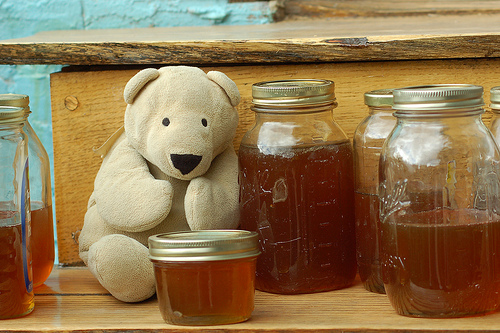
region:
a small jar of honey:
[139, 209, 281, 327]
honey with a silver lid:
[120, 199, 255, 324]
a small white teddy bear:
[62, 77, 242, 285]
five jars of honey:
[177, 70, 497, 332]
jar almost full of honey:
[244, 87, 351, 297]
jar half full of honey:
[346, 89, 488, 304]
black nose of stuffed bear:
[147, 143, 210, 188]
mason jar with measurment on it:
[222, 75, 340, 312]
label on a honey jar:
[17, 157, 48, 326]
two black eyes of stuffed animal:
[135, 105, 215, 137]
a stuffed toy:
[77, 101, 180, 331]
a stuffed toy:
[159, 34, 244, 215]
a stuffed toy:
[102, 56, 230, 328]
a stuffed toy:
[192, 110, 294, 280]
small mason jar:
[129, 223, 286, 308]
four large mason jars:
[242, 58, 495, 264]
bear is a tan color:
[74, 53, 257, 320]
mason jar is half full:
[383, 135, 498, 280]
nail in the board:
[59, 83, 83, 125]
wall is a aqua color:
[46, 7, 174, 34]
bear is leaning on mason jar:
[149, 58, 274, 243]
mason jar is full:
[229, 94, 382, 322]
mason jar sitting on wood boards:
[10, 221, 497, 314]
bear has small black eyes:
[160, 106, 209, 139]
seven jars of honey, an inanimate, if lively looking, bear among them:
[0, 61, 499, 320]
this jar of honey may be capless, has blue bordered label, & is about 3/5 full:
[0, 99, 42, 326]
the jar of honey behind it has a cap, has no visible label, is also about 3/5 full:
[0, 88, 64, 292]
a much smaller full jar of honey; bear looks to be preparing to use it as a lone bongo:
[143, 220, 271, 331]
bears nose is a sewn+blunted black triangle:
[164, 150, 206, 176]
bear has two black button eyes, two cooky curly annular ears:
[113, 62, 245, 133]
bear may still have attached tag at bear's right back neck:
[83, 120, 127, 160]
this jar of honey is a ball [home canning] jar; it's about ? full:
[231, 63, 364, 300]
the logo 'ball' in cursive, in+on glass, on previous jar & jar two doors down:
[233, 153, 445, 236]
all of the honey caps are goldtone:
[0, 57, 499, 332]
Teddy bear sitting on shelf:
[87, 40, 273, 304]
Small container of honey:
[130, 227, 325, 319]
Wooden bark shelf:
[1, 35, 498, 67]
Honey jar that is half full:
[387, 85, 498, 305]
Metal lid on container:
[150, 211, 276, 268]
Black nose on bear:
[163, 137, 218, 186]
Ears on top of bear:
[115, 59, 250, 117]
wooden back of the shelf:
[47, 67, 82, 122]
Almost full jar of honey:
[230, 73, 362, 303]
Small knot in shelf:
[325, 29, 396, 56]